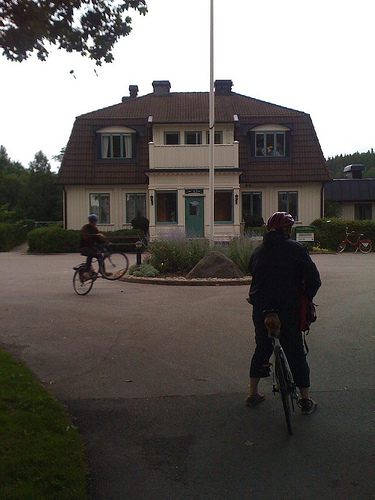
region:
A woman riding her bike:
[250, 206, 331, 462]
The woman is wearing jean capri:
[249, 302, 330, 397]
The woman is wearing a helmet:
[257, 199, 298, 242]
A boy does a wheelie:
[51, 216, 144, 295]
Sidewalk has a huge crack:
[42, 342, 239, 492]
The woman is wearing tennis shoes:
[239, 365, 275, 414]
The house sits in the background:
[60, 94, 373, 227]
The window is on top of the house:
[251, 118, 291, 158]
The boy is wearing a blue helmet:
[79, 210, 99, 226]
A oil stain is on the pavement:
[131, 431, 223, 495]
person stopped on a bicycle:
[245, 209, 330, 446]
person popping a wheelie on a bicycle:
[65, 210, 128, 291]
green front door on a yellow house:
[181, 186, 208, 239]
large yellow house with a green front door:
[59, 73, 329, 251]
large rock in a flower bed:
[182, 246, 245, 283]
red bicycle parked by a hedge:
[335, 225, 374, 256]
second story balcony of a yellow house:
[146, 110, 242, 172]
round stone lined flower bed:
[112, 238, 251, 289]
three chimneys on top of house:
[118, 69, 236, 100]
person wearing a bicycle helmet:
[263, 207, 297, 240]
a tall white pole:
[203, 2, 224, 247]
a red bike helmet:
[266, 208, 296, 230]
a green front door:
[184, 196, 207, 236]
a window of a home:
[255, 133, 288, 156]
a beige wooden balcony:
[147, 142, 239, 169]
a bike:
[69, 248, 130, 294]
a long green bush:
[27, 223, 142, 253]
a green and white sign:
[291, 222, 319, 247]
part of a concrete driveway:
[313, 252, 373, 390]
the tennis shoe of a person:
[301, 398, 320, 415]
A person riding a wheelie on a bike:
[67, 213, 131, 295]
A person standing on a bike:
[236, 206, 331, 464]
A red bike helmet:
[256, 211, 305, 240]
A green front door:
[182, 189, 210, 246]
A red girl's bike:
[333, 225, 373, 259]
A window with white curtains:
[96, 127, 141, 163]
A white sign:
[294, 225, 320, 254]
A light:
[131, 238, 146, 270]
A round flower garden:
[123, 232, 263, 283]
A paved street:
[13, 284, 374, 484]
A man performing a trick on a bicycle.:
[60, 206, 137, 312]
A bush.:
[22, 221, 76, 251]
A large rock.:
[180, 242, 241, 288]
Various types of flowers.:
[145, 225, 254, 273]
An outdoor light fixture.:
[126, 234, 144, 267]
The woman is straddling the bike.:
[226, 197, 331, 426]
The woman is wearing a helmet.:
[260, 210, 295, 240]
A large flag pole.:
[195, 0, 221, 247]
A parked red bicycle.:
[330, 221, 372, 258]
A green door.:
[180, 189, 207, 239]